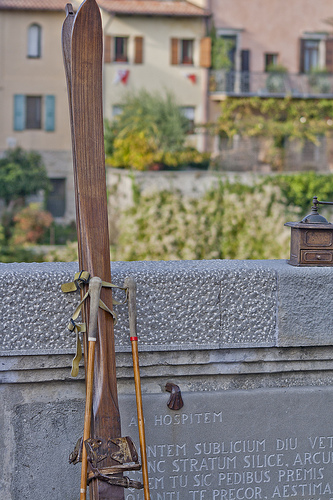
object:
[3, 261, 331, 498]
slab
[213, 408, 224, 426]
letter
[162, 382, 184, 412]
bracket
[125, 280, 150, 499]
handle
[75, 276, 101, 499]
handle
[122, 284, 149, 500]
ski poles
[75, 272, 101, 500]
ski poles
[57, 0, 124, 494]
together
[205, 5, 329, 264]
builduing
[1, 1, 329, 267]
background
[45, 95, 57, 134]
shutter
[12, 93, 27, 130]
shutter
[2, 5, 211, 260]
builduing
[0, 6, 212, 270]
left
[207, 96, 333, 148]
plant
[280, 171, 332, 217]
plant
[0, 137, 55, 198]
plant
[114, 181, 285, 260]
shrubbery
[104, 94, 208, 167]
shrubbery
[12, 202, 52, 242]
shrubbery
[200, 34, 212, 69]
shutter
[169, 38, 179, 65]
shutter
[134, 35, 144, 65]
shutter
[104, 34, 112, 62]
shutter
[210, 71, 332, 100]
balcony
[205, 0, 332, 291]
right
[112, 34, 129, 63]
window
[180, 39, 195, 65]
window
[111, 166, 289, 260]
wall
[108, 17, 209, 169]
wall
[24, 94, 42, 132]
window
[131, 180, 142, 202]
leaves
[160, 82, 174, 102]
leaves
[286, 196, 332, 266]
grinder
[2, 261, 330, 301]
top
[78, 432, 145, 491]
straps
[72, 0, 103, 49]
top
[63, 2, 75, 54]
top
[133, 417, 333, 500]
ingrave